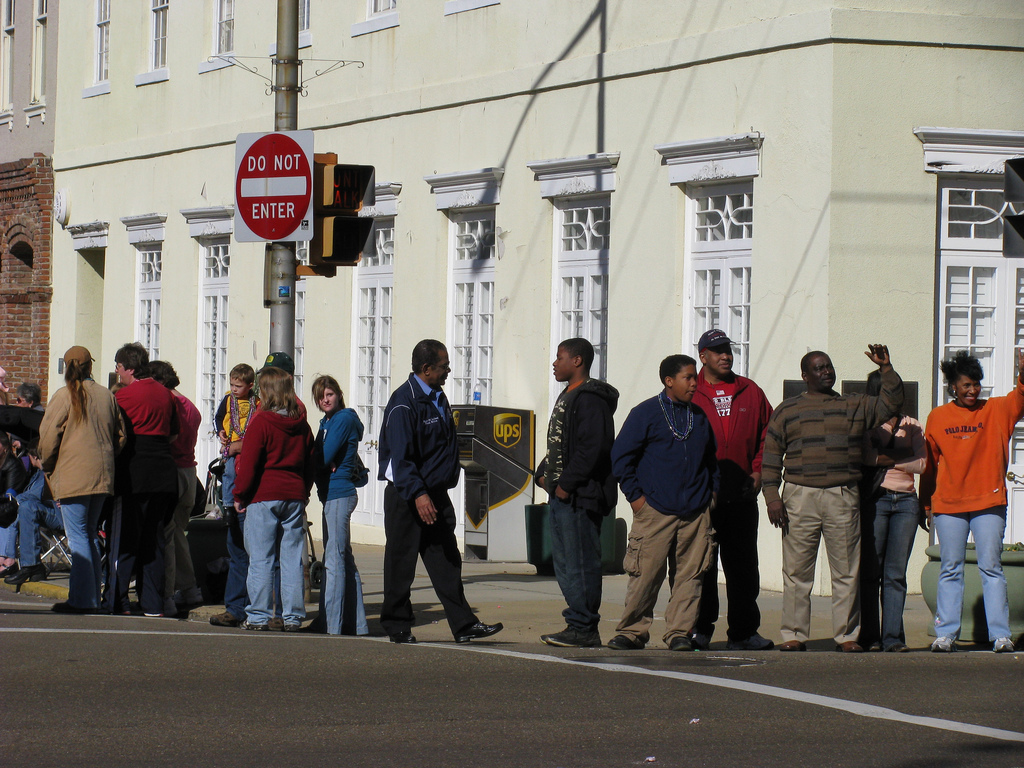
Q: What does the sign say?
A: Do not enter.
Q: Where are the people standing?
A: On a street.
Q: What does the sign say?
A: Do Not Enter.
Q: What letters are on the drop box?
A: UPS.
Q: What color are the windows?
A: White.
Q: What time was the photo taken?
A: Morning.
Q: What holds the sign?
A: A pole.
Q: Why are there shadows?
A: The sun is out.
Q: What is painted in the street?
A: A crosswalk.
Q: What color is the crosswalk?
A: White.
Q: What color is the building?
A: Cream.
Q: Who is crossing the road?
A: A man is.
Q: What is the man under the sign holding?
A: A child.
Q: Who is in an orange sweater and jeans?
A: The woman on the far right.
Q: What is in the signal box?
A: Traffic lights.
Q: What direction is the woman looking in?
A: To her left.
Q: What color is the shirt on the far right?
A: Orange.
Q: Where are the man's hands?
A: In the pockets.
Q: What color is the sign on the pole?
A: It is red and white.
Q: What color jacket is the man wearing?
A: Red.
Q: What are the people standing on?
A: They are standing on the curb.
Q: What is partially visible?
A: A brick building.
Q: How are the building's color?
A: They are slightly darker than paint on windows.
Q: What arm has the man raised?
A: The left arm.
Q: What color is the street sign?
A: Red and white.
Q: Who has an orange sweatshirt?
A: The woman.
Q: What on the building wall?
A: Windows.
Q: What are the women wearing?
A: Sweatshirts.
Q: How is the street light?
A: Its old yellow.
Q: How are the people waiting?
A: In line.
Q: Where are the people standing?
A: On the street corner.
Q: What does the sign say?
A: Do not enter.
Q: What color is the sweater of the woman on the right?
A: Orange.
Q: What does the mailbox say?
A: Ups.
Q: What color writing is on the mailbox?
A: Yellow.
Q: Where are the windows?
A: On the building in the background.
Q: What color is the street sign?
A: Red and white.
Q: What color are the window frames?
A: White.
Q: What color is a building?
A: White.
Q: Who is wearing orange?
A: Woman on right.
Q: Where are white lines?
A: On the road.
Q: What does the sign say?
A: "DO NOT ENTER".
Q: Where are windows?
A: On the building.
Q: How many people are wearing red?
A: Three.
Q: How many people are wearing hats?
A: Two.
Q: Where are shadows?
A: On white building.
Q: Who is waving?
A: Two people.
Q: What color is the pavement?
A: Dark gray.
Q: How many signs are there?
A: One.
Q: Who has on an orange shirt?
A: Man on the right.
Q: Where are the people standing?
A: On the sidewalk.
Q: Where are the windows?
A: On the building.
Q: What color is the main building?
A: Cream.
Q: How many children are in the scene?
A: One.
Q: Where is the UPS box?
A: Next to the building.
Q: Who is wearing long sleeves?
A: Everyone.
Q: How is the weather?
A: Clear.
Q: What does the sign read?
A: Do not enter.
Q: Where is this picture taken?
A: A street.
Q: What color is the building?
A: Yellow.